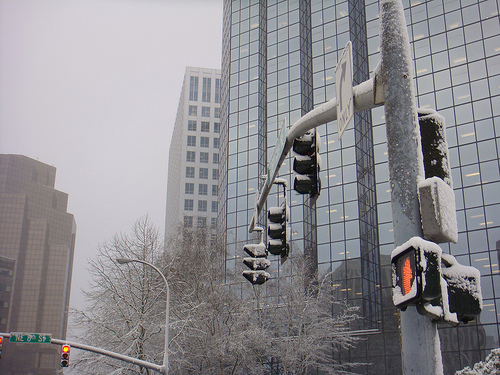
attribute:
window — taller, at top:
[189, 74, 202, 103]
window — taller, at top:
[200, 74, 213, 106]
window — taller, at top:
[213, 74, 221, 106]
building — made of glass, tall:
[216, 1, 500, 373]